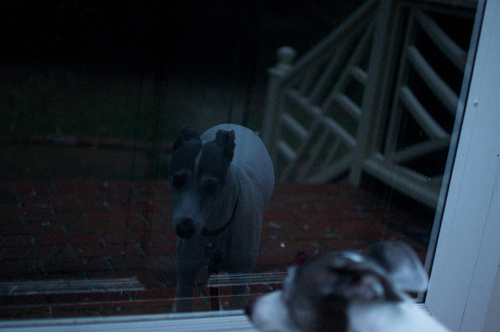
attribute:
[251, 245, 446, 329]
dog — white, reflected, photo, reflection, regular, looking, brown, unhappy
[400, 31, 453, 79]
railing — white, green, reflected, wooden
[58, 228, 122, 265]
pavement — red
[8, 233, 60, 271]
porch — brick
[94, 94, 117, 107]
grass — relfected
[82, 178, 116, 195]
floor — red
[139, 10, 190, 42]
reflection — glare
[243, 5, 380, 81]
room — dark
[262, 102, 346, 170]
stairs — side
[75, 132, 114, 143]
brick — here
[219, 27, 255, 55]
wall — green